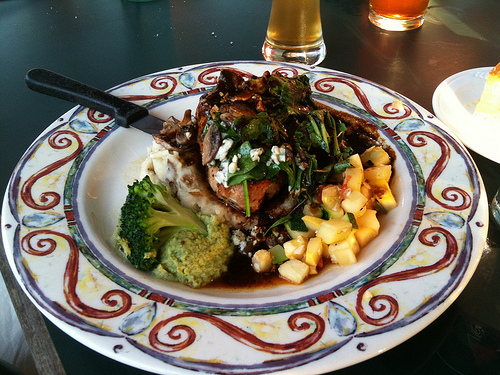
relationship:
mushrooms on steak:
[202, 130, 292, 190] [152, 66, 379, 231]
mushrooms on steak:
[203, 106, 339, 219] [152, 66, 379, 231]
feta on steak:
[210, 135, 291, 186] [152, 66, 379, 231]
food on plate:
[115, 67, 394, 287] [0, 58, 489, 374]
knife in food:
[21, 65, 173, 142] [105, 64, 399, 301]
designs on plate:
[2, 53, 499, 373] [0, 58, 489, 374]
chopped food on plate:
[244, 142, 404, 285] [63, 95, 438, 316]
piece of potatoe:
[303, 236, 320, 266] [304, 237, 321, 267]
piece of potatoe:
[322, 183, 340, 209] [319, 182, 341, 208]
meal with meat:
[72, 91, 413, 279] [215, 69, 317, 131]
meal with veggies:
[72, 91, 413, 279] [114, 181, 325, 271]